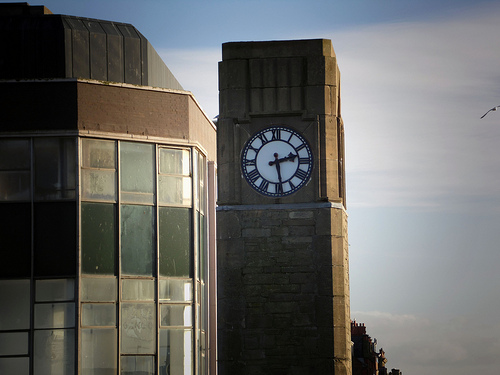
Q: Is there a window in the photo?
A: Yes, there are windows.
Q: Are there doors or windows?
A: Yes, there are windows.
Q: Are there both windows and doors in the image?
A: No, there are windows but no doors.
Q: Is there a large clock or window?
A: Yes, there are large windows.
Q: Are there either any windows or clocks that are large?
A: Yes, the windows are large.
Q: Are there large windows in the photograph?
A: Yes, there are large windows.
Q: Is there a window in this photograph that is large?
A: Yes, there are windows that are large.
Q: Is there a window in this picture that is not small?
A: Yes, there are large windows.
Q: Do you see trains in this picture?
A: No, there are no trains.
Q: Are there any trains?
A: No, there are no trains.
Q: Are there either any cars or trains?
A: No, there are no trains or cars.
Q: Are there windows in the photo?
A: Yes, there are windows.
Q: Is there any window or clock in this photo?
A: Yes, there are windows.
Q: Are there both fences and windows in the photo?
A: No, there are windows but no fences.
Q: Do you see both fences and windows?
A: No, there are windows but no fences.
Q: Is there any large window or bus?
A: Yes, there are large windows.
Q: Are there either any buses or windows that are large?
A: Yes, the windows are large.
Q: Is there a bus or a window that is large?
A: Yes, the windows are large.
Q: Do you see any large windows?
A: Yes, there are large windows.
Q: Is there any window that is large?
A: Yes, there are windows that are large.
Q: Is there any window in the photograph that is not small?
A: Yes, there are large windows.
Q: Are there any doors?
A: No, there are no doors.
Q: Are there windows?
A: Yes, there are windows.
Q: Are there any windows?
A: Yes, there are windows.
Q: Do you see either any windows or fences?
A: Yes, there are windows.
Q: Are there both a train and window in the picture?
A: No, there are windows but no trains.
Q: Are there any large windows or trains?
A: Yes, there are large windows.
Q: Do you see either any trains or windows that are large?
A: Yes, the windows are large.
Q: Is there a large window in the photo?
A: Yes, there are large windows.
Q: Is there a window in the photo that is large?
A: Yes, there are windows that are large.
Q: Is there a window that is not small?
A: Yes, there are large windows.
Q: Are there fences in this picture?
A: No, there are no fences.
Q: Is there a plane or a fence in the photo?
A: No, there are no fences or airplanes.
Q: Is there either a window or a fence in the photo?
A: Yes, there are windows.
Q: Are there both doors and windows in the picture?
A: No, there are windows but no doors.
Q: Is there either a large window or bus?
A: Yes, there are large windows.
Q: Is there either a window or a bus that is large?
A: Yes, the windows are large.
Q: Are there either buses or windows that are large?
A: Yes, the windows are large.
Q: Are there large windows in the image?
A: Yes, there are large windows.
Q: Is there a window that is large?
A: Yes, there are windows that are large.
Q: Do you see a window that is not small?
A: Yes, there are large windows.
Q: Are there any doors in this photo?
A: No, there are no doors.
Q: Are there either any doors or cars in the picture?
A: No, there are no doors or cars.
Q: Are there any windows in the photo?
A: Yes, there are windows.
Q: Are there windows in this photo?
A: Yes, there are windows.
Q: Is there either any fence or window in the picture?
A: Yes, there are windows.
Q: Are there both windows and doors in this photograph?
A: No, there are windows but no doors.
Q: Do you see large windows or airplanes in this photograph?
A: Yes, there are large windows.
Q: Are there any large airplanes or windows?
A: Yes, there are large windows.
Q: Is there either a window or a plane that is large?
A: Yes, the windows are large.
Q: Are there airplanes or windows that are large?
A: Yes, the windows are large.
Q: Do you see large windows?
A: Yes, there are large windows.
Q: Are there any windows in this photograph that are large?
A: Yes, there are windows that are large.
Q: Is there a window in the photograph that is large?
A: Yes, there are windows that are large.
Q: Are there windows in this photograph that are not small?
A: Yes, there are large windows.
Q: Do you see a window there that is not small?
A: Yes, there are large windows.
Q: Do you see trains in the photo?
A: No, there are no trains.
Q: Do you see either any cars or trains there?
A: No, there are no trains or cars.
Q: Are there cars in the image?
A: No, there are no cars.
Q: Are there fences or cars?
A: No, there are no cars or fences.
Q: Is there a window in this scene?
A: Yes, there is a window.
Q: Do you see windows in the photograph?
A: Yes, there is a window.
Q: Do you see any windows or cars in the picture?
A: Yes, there is a window.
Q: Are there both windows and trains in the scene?
A: No, there is a window but no trains.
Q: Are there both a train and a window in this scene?
A: No, there is a window but no trains.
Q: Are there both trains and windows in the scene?
A: No, there is a window but no trains.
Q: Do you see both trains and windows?
A: No, there is a window but no trains.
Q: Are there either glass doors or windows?
A: Yes, there is a glass window.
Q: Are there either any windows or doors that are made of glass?
A: Yes, the window is made of glass.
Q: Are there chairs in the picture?
A: No, there are no chairs.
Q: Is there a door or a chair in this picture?
A: No, there are no chairs or doors.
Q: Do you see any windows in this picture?
A: Yes, there are windows.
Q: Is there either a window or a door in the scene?
A: Yes, there are windows.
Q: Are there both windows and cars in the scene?
A: No, there are windows but no cars.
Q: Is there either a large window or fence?
A: Yes, there are large windows.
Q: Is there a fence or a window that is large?
A: Yes, the windows are large.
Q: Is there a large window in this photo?
A: Yes, there are large windows.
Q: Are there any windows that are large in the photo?
A: Yes, there are large windows.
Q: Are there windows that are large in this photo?
A: Yes, there are large windows.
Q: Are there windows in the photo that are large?
A: Yes, there are large windows.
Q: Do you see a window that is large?
A: Yes, there are windows that are large.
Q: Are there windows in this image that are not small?
A: Yes, there are large windows.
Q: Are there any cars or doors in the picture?
A: No, there are no cars or doors.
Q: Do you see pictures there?
A: No, there are no pictures.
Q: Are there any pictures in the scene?
A: No, there are no pictures.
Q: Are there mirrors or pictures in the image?
A: No, there are no pictures or mirrors.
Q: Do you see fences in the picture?
A: No, there are no fences.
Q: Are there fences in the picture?
A: No, there are no fences.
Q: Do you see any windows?
A: Yes, there are windows.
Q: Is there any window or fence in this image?
A: Yes, there are windows.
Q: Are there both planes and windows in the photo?
A: No, there are windows but no airplanes.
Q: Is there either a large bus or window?
A: Yes, there are large windows.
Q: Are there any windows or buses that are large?
A: Yes, the windows are large.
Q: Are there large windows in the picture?
A: Yes, there are large windows.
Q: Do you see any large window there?
A: Yes, there are large windows.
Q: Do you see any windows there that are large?
A: Yes, there are windows that are large.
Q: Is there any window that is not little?
A: Yes, there are large windows.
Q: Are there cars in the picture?
A: No, there are no cars.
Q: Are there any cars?
A: No, there are no cars.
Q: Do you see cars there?
A: No, there are no cars.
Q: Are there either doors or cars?
A: No, there are no cars or doors.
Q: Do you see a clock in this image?
A: Yes, there is a clock.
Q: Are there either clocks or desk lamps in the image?
A: Yes, there is a clock.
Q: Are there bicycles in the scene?
A: No, there are no bicycles.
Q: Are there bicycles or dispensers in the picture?
A: No, there are no bicycles or dispensers.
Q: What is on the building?
A: The clock is on the building.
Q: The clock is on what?
A: The clock is on the building.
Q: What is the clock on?
A: The clock is on the building.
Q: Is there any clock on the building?
A: Yes, there is a clock on the building.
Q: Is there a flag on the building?
A: No, there is a clock on the building.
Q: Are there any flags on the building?
A: No, there is a clock on the building.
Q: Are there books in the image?
A: No, there are no books.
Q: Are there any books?
A: No, there are no books.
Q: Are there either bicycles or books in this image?
A: No, there are no books or bicycles.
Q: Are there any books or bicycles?
A: No, there are no books or bicycles.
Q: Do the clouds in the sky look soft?
A: Yes, the clouds are soft.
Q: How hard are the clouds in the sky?
A: The clouds are soft.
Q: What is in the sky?
A: The clouds are in the sky.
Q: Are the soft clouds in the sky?
A: Yes, the clouds are in the sky.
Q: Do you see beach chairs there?
A: No, there are no beach chairs.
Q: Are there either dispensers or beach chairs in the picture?
A: No, there are no beach chairs or dispensers.